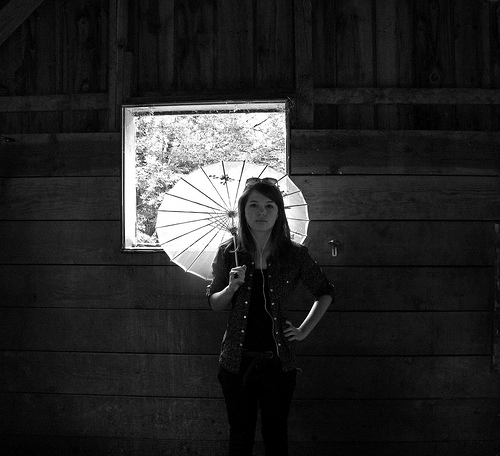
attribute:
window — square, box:
[122, 102, 289, 252]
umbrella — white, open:
[160, 160, 318, 285]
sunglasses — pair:
[244, 175, 288, 193]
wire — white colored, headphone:
[256, 245, 280, 364]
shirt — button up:
[215, 239, 336, 371]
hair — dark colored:
[235, 174, 291, 259]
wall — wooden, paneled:
[328, 120, 458, 416]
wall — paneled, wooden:
[15, 139, 129, 402]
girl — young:
[208, 178, 336, 436]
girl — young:
[208, 177, 348, 428]